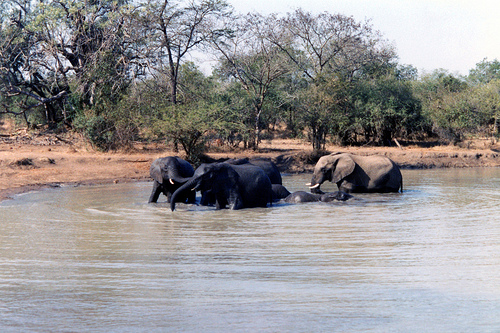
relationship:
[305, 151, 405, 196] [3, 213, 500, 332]
elephant in water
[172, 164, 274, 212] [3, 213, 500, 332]
elephant in water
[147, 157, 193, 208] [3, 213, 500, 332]
elephant in water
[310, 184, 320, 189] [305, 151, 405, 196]
tusks on elephant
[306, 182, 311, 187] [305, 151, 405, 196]
tusks on elephant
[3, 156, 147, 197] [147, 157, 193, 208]
ground behind elephant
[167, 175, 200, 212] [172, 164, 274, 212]
trunk on elephant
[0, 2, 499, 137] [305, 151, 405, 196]
trees behind elephant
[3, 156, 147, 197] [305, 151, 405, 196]
ground behind elephant